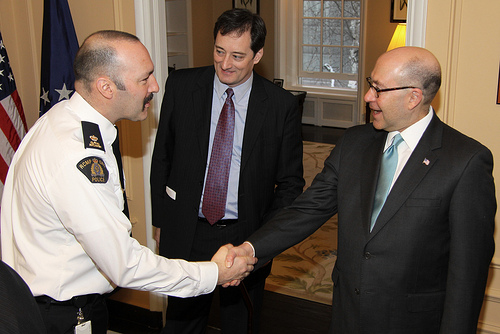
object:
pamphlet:
[162, 185, 179, 200]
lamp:
[386, 23, 411, 50]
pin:
[418, 155, 431, 172]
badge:
[75, 154, 110, 184]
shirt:
[0, 92, 217, 301]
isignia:
[80, 112, 103, 147]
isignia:
[75, 155, 112, 188]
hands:
[207, 239, 258, 287]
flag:
[36, 10, 76, 98]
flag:
[1, 31, 30, 185]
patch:
[75, 153, 109, 183]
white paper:
[163, 184, 177, 201]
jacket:
[150, 61, 307, 255]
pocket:
[160, 192, 176, 216]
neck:
[210, 68, 256, 90]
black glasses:
[367, 75, 419, 95]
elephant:
[74, 153, 113, 186]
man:
[304, 39, 500, 334]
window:
[289, 1, 365, 96]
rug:
[257, 113, 370, 308]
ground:
[403, 97, 428, 125]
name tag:
[64, 306, 99, 332]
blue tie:
[368, 134, 402, 232]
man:
[149, 5, 309, 332]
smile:
[216, 66, 238, 76]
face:
[212, 40, 251, 85]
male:
[0, 31, 260, 331]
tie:
[354, 132, 407, 229]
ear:
[249, 39, 271, 67]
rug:
[274, 218, 331, 310]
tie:
[203, 85, 238, 221]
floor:
[262, 127, 353, 303]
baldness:
[75, 24, 148, 72]